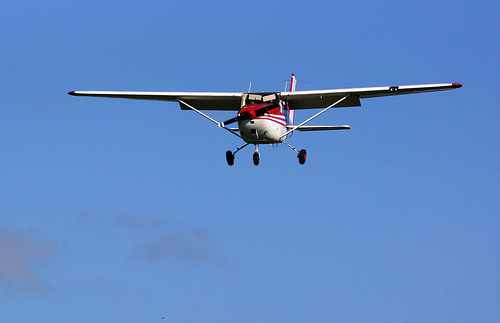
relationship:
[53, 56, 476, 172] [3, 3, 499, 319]
airplane flying in sky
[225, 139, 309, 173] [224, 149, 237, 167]
landing gear has wheel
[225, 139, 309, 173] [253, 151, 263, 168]
landing gear has wheel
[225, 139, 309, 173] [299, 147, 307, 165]
landing gear has wheel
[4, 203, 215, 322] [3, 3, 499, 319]
cloud in sky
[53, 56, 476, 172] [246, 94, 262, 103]
airplane has window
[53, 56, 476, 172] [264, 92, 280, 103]
airplane has window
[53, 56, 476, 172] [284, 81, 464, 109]
airplane has wing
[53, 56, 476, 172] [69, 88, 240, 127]
airplane has wing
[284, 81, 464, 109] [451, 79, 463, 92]
wing has tip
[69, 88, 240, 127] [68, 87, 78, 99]
wing has tip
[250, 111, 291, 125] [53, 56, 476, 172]
stripe on side of airplane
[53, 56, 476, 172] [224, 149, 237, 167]
airplane has wheel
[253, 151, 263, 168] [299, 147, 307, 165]
wheel next to wheel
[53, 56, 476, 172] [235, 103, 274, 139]
airplane has nose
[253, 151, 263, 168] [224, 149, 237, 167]
wheel next to wheel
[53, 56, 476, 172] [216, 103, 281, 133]
airplane has propeller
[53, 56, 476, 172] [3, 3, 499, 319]
airplane in sky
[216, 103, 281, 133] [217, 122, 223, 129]
propeller has stripe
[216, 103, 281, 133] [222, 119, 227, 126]
propeller has stripe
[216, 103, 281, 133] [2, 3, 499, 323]
propeller on front of airplane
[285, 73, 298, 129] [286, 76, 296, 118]
tail has stripe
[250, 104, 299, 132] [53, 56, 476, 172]
stripe on side of airplane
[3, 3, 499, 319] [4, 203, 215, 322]
sky has cloud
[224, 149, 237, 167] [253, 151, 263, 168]
wheel next to wheel